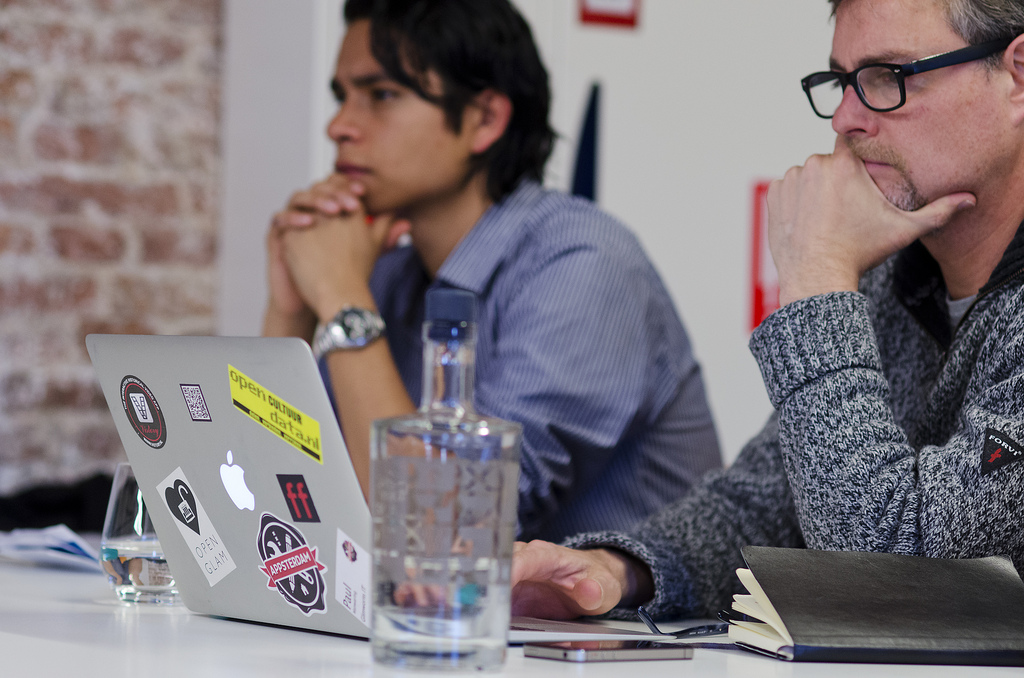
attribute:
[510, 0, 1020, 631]
person — sitting down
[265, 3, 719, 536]
person — sitting down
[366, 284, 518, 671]
bottle — for holding liquid, clear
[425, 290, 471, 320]
cap — blue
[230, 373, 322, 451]
sticker — rectangular, yellow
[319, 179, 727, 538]
button down — blue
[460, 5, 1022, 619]
man — serious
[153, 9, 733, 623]
person — sitting down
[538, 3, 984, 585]
person — sitting down